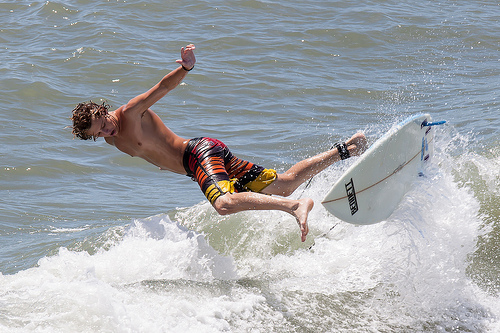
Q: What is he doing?
A: Surfing.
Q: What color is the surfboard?
A: White.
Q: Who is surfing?
A: A man.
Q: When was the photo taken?
A: Day time.